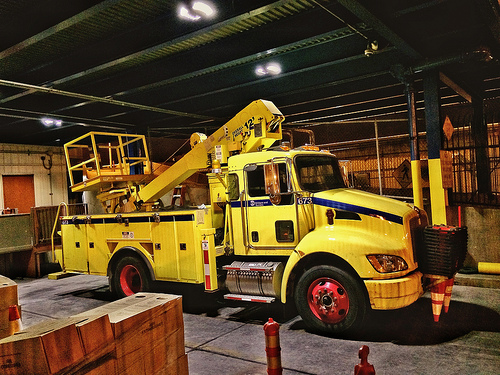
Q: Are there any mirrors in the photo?
A: Yes, there is a mirror.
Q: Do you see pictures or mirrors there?
A: Yes, there is a mirror.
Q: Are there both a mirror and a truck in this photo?
A: Yes, there are both a mirror and a truck.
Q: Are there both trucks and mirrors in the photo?
A: Yes, there are both a mirror and a truck.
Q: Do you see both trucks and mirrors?
A: Yes, there are both a mirror and a truck.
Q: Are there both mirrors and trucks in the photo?
A: Yes, there are both a mirror and a truck.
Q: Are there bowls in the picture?
A: No, there are no bowls.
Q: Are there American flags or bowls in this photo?
A: No, there are no bowls or American flags.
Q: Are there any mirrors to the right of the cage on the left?
A: Yes, there is a mirror to the right of the cage.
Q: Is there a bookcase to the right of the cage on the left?
A: No, there is a mirror to the right of the cage.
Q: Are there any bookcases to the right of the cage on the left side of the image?
A: No, there is a mirror to the right of the cage.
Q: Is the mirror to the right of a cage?
A: Yes, the mirror is to the right of a cage.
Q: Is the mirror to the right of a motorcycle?
A: No, the mirror is to the right of a cage.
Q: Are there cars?
A: No, there are no cars.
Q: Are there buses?
A: No, there are no buses.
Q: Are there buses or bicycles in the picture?
A: No, there are no buses or bicycles.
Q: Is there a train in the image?
A: No, there are no trains.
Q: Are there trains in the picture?
A: No, there are no trains.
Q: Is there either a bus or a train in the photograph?
A: No, there are no trains or buses.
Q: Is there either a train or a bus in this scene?
A: No, there are no trains or buses.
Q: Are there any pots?
A: No, there are no pots.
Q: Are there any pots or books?
A: No, there are no pots or books.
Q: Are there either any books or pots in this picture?
A: No, there are no pots or books.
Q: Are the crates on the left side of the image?
A: Yes, the crates are on the left of the image.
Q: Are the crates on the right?
A: No, the crates are on the left of the image.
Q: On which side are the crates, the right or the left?
A: The crates are on the left of the image.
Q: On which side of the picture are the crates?
A: The crates are on the left of the image.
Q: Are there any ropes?
A: No, there are no ropes.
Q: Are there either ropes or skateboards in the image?
A: No, there are no ropes or skateboards.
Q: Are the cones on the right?
A: Yes, the cones are on the right of the image.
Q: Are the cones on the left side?
A: No, the cones are on the right of the image.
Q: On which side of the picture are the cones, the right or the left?
A: The cones are on the right of the image.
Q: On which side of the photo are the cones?
A: The cones are on the right of the image.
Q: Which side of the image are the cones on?
A: The cones are on the right of the image.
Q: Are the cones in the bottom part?
A: Yes, the cones are in the bottom of the image.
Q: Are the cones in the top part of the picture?
A: No, the cones are in the bottom of the image.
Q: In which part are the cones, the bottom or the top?
A: The cones are in the bottom of the image.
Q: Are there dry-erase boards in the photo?
A: No, there are no dry-erase boards.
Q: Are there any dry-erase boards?
A: No, there are no dry-erase boards.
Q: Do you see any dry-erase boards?
A: No, there are no dry-erase boards.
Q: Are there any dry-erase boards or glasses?
A: No, there are no dry-erase boards or glasses.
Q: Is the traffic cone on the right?
A: Yes, the traffic cone is on the right of the image.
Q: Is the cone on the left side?
A: No, the cone is on the right of the image.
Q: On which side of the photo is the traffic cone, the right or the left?
A: The traffic cone is on the right of the image.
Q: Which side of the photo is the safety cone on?
A: The safety cone is on the right of the image.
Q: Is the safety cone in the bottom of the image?
A: Yes, the safety cone is in the bottom of the image.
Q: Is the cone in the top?
A: No, the cone is in the bottom of the image.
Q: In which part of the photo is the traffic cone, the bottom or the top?
A: The traffic cone is in the bottom of the image.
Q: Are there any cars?
A: No, there are no cars.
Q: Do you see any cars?
A: No, there are no cars.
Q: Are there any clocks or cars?
A: No, there are no cars or clocks.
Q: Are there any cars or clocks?
A: No, there are no cars or clocks.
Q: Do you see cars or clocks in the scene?
A: No, there are no cars or clocks.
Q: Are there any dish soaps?
A: No, there are no dish soaps.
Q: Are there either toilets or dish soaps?
A: No, there are no dish soaps or toilets.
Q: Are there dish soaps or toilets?
A: No, there are no dish soaps or toilets.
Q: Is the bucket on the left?
A: Yes, the bucket is on the left of the image.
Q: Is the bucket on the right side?
A: No, the bucket is on the left of the image.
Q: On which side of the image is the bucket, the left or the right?
A: The bucket is on the left of the image.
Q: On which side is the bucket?
A: The bucket is on the left of the image.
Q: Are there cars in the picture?
A: No, there are no cars.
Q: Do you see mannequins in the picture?
A: No, there are no mannequins.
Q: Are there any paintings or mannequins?
A: No, there are no mannequins or paintings.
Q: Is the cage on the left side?
A: Yes, the cage is on the left of the image.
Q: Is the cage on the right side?
A: No, the cage is on the left of the image.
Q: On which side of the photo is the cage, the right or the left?
A: The cage is on the left of the image.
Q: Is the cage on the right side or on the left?
A: The cage is on the left of the image.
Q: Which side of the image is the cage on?
A: The cage is on the left of the image.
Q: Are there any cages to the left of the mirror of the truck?
A: Yes, there is a cage to the left of the mirror.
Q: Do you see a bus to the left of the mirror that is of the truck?
A: No, there is a cage to the left of the mirror.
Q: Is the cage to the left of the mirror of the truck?
A: Yes, the cage is to the left of the mirror.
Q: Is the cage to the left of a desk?
A: No, the cage is to the left of the mirror.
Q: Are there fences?
A: Yes, there is a fence.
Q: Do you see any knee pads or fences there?
A: Yes, there is a fence.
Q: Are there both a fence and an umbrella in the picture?
A: No, there is a fence but no umbrellas.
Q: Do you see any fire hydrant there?
A: No, there are no fire hydrants.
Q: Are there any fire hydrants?
A: No, there are no fire hydrants.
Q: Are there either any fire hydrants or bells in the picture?
A: No, there are no fire hydrants or bells.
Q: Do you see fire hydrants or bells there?
A: No, there are no fire hydrants or bells.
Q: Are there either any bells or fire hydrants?
A: No, there are no fire hydrants or bells.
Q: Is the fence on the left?
A: Yes, the fence is on the left of the image.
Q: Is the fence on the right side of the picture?
A: No, the fence is on the left of the image.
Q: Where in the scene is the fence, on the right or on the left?
A: The fence is on the left of the image.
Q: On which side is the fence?
A: The fence is on the left of the image.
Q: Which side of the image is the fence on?
A: The fence is on the left of the image.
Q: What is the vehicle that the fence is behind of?
A: The vehicle is a truck.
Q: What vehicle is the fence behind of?
A: The fence is behind the truck.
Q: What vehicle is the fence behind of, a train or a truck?
A: The fence is behind a truck.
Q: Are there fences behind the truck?
A: Yes, there is a fence behind the truck.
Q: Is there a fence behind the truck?
A: Yes, there is a fence behind the truck.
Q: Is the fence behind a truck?
A: Yes, the fence is behind a truck.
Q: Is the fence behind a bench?
A: No, the fence is behind a truck.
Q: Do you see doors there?
A: Yes, there is a door.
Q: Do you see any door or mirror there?
A: Yes, there is a door.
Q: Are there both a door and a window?
A: Yes, there are both a door and a window.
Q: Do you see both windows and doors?
A: Yes, there are both a door and a window.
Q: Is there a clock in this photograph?
A: No, there are no clocks.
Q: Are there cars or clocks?
A: No, there are no clocks or cars.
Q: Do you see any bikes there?
A: No, there are no bikes.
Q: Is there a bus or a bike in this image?
A: No, there are no bikes or buses.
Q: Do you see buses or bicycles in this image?
A: No, there are no bicycles or buses.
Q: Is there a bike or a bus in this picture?
A: No, there are no bikes or buses.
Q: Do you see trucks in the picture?
A: Yes, there is a truck.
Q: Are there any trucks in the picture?
A: Yes, there is a truck.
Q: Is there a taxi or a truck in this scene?
A: Yes, there is a truck.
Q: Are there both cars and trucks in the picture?
A: No, there is a truck but no cars.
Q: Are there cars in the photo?
A: No, there are no cars.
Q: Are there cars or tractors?
A: No, there are no cars or tractors.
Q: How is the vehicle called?
A: The vehicle is a truck.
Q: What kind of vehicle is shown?
A: The vehicle is a truck.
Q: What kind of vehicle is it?
A: The vehicle is a truck.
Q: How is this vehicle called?
A: This is a truck.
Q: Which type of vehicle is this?
A: This is a truck.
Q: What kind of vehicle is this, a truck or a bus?
A: This is a truck.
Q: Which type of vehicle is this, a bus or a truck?
A: This is a truck.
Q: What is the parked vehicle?
A: The vehicle is a truck.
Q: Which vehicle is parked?
A: The vehicle is a truck.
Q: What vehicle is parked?
A: The vehicle is a truck.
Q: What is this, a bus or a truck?
A: This is a truck.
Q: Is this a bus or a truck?
A: This is a truck.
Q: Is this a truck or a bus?
A: This is a truck.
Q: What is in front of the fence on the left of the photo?
A: The truck is in front of the fence.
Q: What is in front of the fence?
A: The truck is in front of the fence.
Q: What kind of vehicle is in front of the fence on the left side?
A: The vehicle is a truck.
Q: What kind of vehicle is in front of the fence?
A: The vehicle is a truck.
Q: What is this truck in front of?
A: The truck is in front of the fence.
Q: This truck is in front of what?
A: The truck is in front of the fence.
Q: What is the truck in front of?
A: The truck is in front of the fence.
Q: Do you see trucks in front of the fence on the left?
A: Yes, there is a truck in front of the fence.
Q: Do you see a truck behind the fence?
A: No, the truck is in front of the fence.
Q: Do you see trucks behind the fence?
A: No, the truck is in front of the fence.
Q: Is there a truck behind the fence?
A: No, the truck is in front of the fence.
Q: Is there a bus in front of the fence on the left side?
A: No, there is a truck in front of the fence.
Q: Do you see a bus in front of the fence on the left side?
A: No, there is a truck in front of the fence.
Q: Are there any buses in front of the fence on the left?
A: No, there is a truck in front of the fence.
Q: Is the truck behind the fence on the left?
A: No, the truck is in front of the fence.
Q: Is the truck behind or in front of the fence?
A: The truck is in front of the fence.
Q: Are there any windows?
A: Yes, there is a window.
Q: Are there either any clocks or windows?
A: Yes, there is a window.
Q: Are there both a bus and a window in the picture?
A: No, there is a window but no buses.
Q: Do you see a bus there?
A: No, there are no buses.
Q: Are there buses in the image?
A: No, there are no buses.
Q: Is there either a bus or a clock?
A: No, there are no buses or clocks.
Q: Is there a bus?
A: No, there are no buses.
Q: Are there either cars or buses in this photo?
A: No, there are no buses or cars.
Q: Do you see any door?
A: Yes, there is a door.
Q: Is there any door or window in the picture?
A: Yes, there is a door.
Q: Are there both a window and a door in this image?
A: Yes, there are both a door and a window.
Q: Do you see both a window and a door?
A: Yes, there are both a door and a window.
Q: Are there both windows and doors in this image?
A: Yes, there are both a door and a window.